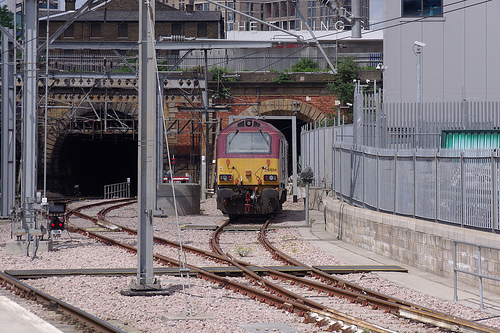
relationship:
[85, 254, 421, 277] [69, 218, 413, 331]
plank across track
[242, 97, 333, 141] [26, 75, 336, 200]
arch in wall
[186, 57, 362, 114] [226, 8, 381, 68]
bushes in front of building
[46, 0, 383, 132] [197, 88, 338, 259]
buildings behind train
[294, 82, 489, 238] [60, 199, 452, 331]
fencing lining tracks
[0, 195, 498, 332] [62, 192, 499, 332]
gravel lining tracks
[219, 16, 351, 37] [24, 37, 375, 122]
letters standing above bridge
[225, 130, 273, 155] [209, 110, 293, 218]
windowshield on front train